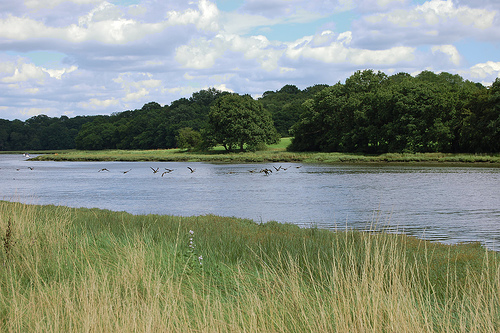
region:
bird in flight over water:
[179, 158, 205, 183]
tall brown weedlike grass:
[343, 264, 420, 325]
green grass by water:
[216, 219, 262, 249]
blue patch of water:
[377, 183, 419, 207]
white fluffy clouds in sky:
[100, 20, 152, 48]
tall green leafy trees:
[371, 89, 428, 131]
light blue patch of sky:
[33, 52, 71, 72]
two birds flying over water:
[13, 161, 38, 183]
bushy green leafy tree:
[214, 88, 269, 133]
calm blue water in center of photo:
[283, 180, 485, 222]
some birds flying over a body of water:
[98, 165, 201, 178]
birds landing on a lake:
[253, 157, 303, 177]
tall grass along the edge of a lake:
[1, 202, 498, 330]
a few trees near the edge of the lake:
[209, 93, 276, 154]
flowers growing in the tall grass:
[186, 227, 208, 277]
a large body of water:
[4, 152, 499, 258]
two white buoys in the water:
[19, 149, 33, 159]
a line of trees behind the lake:
[4, 67, 499, 152]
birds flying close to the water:
[96, 165, 201, 177]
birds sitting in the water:
[249, 159, 275, 180]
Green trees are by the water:
[98, 62, 465, 215]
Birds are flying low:
[70, 138, 367, 193]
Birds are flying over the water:
[92, 153, 438, 195]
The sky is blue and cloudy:
[12, 67, 157, 132]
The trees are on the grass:
[82, 111, 392, 214]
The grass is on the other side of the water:
[57, 138, 269, 164]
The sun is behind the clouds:
[102, 8, 392, 109]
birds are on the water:
[96, 144, 321, 206]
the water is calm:
[160, 145, 374, 234]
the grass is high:
[27, 226, 405, 319]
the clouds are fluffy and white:
[30, 10, 466, 81]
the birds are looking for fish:
[131, 148, 303, 196]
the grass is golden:
[122, 235, 424, 328]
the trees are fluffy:
[276, 60, 496, 145]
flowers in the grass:
[156, 201, 221, 297]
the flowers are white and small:
[168, 219, 214, 274]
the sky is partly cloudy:
[31, 0, 451, 102]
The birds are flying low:
[133, 146, 218, 196]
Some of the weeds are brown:
[75, 270, 140, 319]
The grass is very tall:
[132, 223, 275, 303]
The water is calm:
[267, 187, 402, 246]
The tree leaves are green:
[199, 99, 292, 174]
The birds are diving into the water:
[242, 160, 289, 190]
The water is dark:
[333, 158, 380, 215]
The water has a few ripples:
[363, 223, 480, 246]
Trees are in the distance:
[38, 103, 170, 155]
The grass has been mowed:
[95, 146, 186, 167]